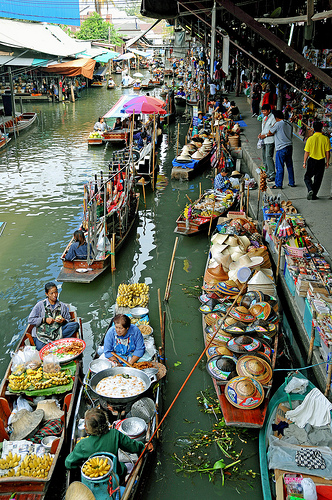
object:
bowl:
[88, 360, 151, 405]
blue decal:
[206, 352, 237, 377]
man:
[300, 112, 332, 205]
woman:
[63, 227, 95, 263]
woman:
[102, 312, 146, 368]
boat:
[75, 282, 163, 403]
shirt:
[102, 326, 146, 360]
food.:
[54, 313, 64, 322]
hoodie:
[102, 313, 146, 369]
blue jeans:
[274, 143, 296, 189]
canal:
[2, 3, 330, 498]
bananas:
[115, 278, 150, 309]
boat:
[55, 160, 141, 287]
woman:
[25, 281, 83, 350]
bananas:
[5, 358, 73, 390]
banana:
[8, 450, 15, 457]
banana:
[13, 453, 17, 461]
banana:
[17, 454, 21, 460]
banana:
[6, 454, 11, 462]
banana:
[9, 459, 13, 467]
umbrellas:
[123, 92, 166, 113]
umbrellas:
[119, 100, 167, 116]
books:
[295, 272, 310, 300]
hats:
[210, 231, 229, 245]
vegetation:
[173, 392, 255, 498]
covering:
[41, 54, 96, 81]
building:
[61, 8, 112, 39]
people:
[229, 100, 243, 122]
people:
[213, 99, 222, 113]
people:
[221, 97, 230, 109]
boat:
[0, 296, 84, 499]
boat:
[199, 207, 279, 430]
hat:
[229, 253, 263, 271]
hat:
[225, 335, 263, 356]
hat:
[236, 355, 273, 386]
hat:
[223, 373, 265, 410]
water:
[1, 49, 304, 500]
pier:
[230, 89, 331, 396]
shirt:
[27, 297, 73, 344]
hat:
[210, 232, 229, 244]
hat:
[224, 235, 240, 248]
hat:
[234, 234, 251, 252]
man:
[257, 103, 276, 182]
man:
[257, 108, 298, 192]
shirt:
[302, 131, 329, 162]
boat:
[63, 279, 168, 500]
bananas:
[84, 452, 115, 477]